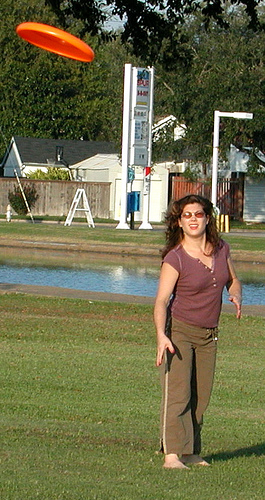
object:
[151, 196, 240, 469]
woman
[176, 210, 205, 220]
sunglasses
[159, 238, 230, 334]
shirt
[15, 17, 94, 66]
frisbee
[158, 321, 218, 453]
pants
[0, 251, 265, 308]
water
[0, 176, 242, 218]
fence